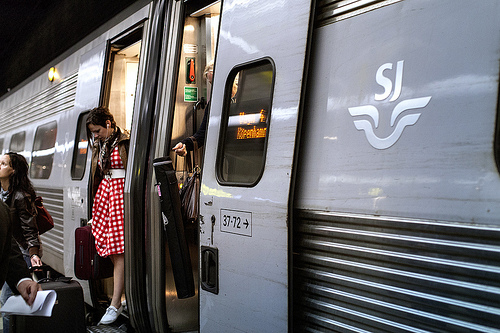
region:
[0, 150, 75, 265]
woman leaving train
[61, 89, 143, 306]
woman stepping down from train onto platform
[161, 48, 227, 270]
man preparing to leave train with carry-on bag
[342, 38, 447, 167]
SJ railroad logo on train car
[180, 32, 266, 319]
open door of train at station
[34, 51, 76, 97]
running light on side of train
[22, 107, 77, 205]
window on car of train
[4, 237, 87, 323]
man holding papers near train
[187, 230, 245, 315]
handle of open train door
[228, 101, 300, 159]
Lighted sign on side of train car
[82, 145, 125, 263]
red and white dress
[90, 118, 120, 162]
person wearing white head phones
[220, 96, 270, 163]
orange writing on window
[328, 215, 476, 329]
silver grate on train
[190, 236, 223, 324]
black handle oin silver door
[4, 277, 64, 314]
a folded white piece of paper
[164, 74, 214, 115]
green and white sign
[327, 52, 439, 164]
the white letters sj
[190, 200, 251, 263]
black numbers 37-72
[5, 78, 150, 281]
two people beside a train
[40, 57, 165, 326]
girl coming off the train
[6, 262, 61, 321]
hand holding paper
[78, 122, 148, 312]
dress is red and white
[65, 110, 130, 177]
girl wearing a scarf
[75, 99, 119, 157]
girl wearing headphones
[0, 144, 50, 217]
woman has long hair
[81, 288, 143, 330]
the shoe is white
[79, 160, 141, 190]
the belt is white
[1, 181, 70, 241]
woman carrying a bag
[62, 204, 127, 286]
the suitcase is red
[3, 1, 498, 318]
a gray train is stop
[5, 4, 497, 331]
train is on a train station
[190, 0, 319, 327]
door of trai is open to the side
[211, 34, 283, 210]
train has a window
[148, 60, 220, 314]
person holding a case of violin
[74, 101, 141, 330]
woman has a brown coat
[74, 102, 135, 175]
hair of woman is dark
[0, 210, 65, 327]
hand holding a white paper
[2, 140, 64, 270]
woman has a red bag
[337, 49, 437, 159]
logotype on train "SJ"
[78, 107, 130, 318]
A woman in a red and white polka dot dress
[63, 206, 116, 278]
A brown bag held by the woman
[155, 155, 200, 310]
an instrument case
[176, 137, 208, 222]
A brown hand bag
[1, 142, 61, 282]
A woman in a brown jacket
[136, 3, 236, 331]
An open train door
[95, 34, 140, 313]
An open train door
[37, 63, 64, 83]
A light on the train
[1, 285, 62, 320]
A piece of paper being held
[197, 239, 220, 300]
the handle on the train door